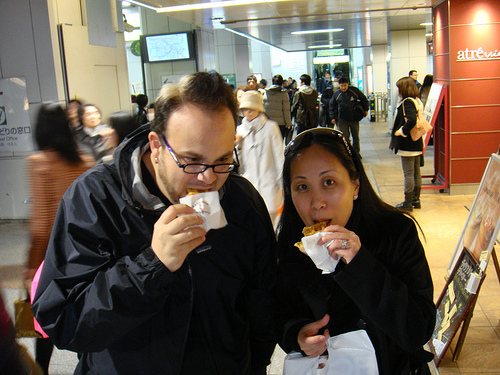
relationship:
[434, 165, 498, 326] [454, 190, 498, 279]
sign with drinks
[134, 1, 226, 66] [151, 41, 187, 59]
television with map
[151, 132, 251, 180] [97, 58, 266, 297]
eyeglasses on man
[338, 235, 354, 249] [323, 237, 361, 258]
ring on finger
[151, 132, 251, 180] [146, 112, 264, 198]
glasses on face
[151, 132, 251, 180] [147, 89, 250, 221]
glasses on head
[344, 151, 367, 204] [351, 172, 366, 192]
earring in ear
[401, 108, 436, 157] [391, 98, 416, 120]
purse on shoulder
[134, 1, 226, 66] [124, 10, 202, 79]
television on wall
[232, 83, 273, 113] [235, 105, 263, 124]
hat on head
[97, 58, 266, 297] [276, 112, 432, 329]
man and woman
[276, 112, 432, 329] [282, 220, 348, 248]
woman has food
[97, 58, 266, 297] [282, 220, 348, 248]
man has food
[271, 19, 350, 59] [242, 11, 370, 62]
lights in ceiling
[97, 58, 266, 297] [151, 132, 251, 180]
man has eyeglasses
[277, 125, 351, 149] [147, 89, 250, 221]
sunglasses on head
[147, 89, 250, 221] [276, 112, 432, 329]
head of woman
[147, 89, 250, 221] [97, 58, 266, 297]
head of man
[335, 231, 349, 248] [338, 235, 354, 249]
part of ring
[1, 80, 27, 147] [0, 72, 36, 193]
part of portrait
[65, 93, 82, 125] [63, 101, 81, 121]
spectacle of man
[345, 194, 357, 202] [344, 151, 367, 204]
part of earring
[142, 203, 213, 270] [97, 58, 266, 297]
hand of man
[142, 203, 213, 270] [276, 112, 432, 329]
hand of woman